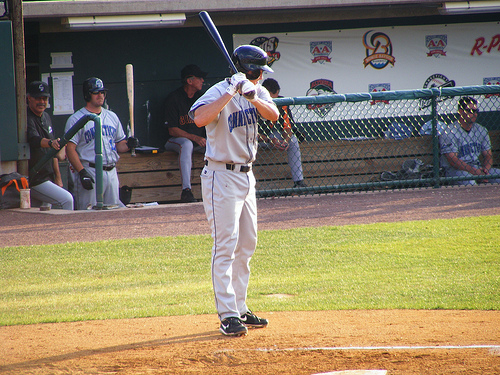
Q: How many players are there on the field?
A: One.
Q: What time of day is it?
A: Daytime.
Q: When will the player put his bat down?
A: After he hits the ball.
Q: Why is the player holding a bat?
A: He is preparing to hit the ball.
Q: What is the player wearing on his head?
A: A helmet.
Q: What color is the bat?
A: Black.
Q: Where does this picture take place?
A: On a baseball field.